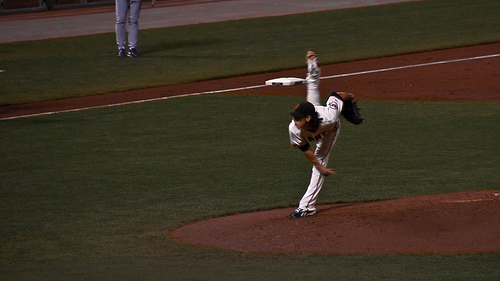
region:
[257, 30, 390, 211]
baseball player on mound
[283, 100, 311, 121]
hat on the player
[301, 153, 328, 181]
arm of the baseball player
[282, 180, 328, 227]
leg of the baseball player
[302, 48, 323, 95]
leg of the baseball player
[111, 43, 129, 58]
leg of baseball player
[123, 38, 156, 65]
leg of baseball player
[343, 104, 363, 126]
glove on baseball player's hand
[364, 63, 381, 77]
white line on field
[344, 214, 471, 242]
pitching mound on field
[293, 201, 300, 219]
part of a shoe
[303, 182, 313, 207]
part of a trouser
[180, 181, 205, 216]
edge of a lawn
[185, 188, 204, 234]
edge of a lawn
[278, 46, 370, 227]
A pitcher at a baseball game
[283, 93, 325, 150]
Pitcher wearing a baseball cap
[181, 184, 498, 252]
Pitcher on pitchers mound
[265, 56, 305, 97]
White base plate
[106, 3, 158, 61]
Players legs wearing white pants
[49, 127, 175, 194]
A large area of green grass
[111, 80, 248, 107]
White chalk line marking area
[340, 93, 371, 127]
A catchers mitt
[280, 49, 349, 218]
Pitcher in white uniform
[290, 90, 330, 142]
Pitcher with dark hair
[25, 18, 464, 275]
this pitcher is throwing a ball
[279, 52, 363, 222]
he is using a unique throwing form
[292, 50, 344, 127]
the pitcher's back leg is extended in the air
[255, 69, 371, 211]
the pitcher's technique is unique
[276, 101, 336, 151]
he wears a black cap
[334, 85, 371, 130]
this is the pitcher's glove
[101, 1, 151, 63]
a person standing on the side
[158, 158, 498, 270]
the pitcher's mound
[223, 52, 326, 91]
this is third base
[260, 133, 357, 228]
this pitcher balances on one leg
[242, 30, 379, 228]
the pitcher on the mound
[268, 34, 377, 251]
the pitcher throwing a baseball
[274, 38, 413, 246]
the pitcher on a baseball field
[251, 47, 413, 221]
the pitcher playing baseball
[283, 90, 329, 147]
the pitcher wearing a cap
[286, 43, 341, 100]
the leg of the pitcher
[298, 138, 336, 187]
the arm of the pitcher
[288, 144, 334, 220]
the leg of the pitcher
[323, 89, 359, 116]
the arm of the pitcher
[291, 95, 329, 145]
the head of the pitcher